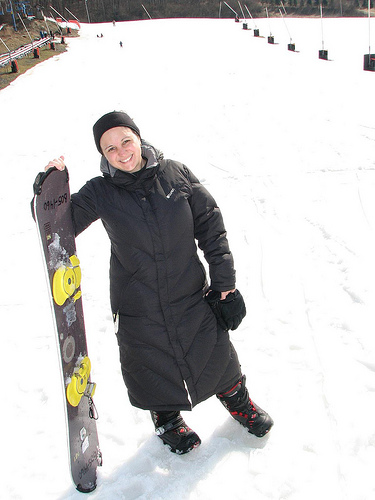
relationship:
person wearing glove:
[30, 109, 276, 457] [207, 286, 245, 331]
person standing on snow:
[30, 109, 276, 457] [0, 18, 375, 497]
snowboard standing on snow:
[34, 155, 103, 494] [0, 18, 375, 497]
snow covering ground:
[178, 76, 319, 147] [15, 12, 373, 496]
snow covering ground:
[4, 19, 375, 499] [261, 64, 372, 495]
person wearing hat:
[30, 109, 276, 457] [91, 108, 144, 156]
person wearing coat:
[30, 109, 276, 457] [30, 139, 236, 412]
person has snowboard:
[30, 109, 276, 457] [29, 156, 106, 494]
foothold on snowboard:
[45, 248, 100, 312] [14, 155, 127, 489]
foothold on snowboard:
[49, 344, 113, 435] [14, 155, 127, 489]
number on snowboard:
[33, 190, 71, 245] [24, 167, 84, 280]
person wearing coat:
[30, 109, 272, 453] [30, 139, 244, 416]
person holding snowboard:
[30, 109, 272, 453] [29, 156, 106, 494]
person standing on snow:
[30, 109, 272, 453] [0, 18, 375, 497]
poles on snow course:
[261, 11, 348, 64] [19, 15, 373, 160]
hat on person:
[76, 96, 165, 163] [30, 109, 276, 457]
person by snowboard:
[30, 109, 276, 457] [34, 155, 103, 494]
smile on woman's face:
[117, 152, 134, 164] [92, 107, 143, 172]